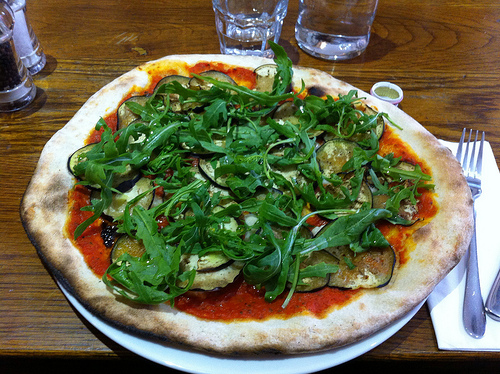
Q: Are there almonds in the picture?
A: No, there are no almonds.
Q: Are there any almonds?
A: No, there are no almonds.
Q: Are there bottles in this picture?
A: No, there are no bottles.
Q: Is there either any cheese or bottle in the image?
A: No, there are no bottles or cheese.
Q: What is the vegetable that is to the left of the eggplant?
A: The vegetable is spinach.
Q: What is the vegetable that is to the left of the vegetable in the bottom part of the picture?
A: The vegetable is spinach.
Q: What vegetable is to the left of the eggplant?
A: The vegetable is spinach.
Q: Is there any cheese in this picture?
A: No, there is no cheese.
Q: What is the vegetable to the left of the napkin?
A: The vegetable is spinach.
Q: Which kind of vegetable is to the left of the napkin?
A: The vegetable is spinach.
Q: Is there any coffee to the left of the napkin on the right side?
A: No, there is spinach to the left of the napkin.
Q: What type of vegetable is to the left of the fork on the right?
A: The vegetable is spinach.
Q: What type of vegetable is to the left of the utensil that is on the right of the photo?
A: The vegetable is spinach.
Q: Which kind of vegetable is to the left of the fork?
A: The vegetable is spinach.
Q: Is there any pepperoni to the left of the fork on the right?
A: No, there is spinach to the left of the fork.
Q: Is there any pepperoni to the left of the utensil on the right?
A: No, there is spinach to the left of the fork.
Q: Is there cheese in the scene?
A: No, there is no cheese.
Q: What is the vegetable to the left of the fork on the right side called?
A: The vegetable is spinach.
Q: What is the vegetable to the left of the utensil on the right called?
A: The vegetable is spinach.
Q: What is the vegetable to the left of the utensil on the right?
A: The vegetable is spinach.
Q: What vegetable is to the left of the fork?
A: The vegetable is spinach.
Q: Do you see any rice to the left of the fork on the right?
A: No, there is spinach to the left of the fork.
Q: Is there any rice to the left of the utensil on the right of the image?
A: No, there is spinach to the left of the fork.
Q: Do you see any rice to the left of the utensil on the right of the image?
A: No, there is spinach to the left of the fork.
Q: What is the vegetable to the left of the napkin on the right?
A: The vegetable is spinach.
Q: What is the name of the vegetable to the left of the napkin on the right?
A: The vegetable is spinach.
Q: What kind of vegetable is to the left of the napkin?
A: The vegetable is spinach.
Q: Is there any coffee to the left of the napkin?
A: No, there is spinach to the left of the napkin.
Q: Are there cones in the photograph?
A: No, there are no cones.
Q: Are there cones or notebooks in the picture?
A: No, there are no cones or notebooks.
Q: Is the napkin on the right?
A: Yes, the napkin is on the right of the image.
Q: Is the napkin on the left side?
A: No, the napkin is on the right of the image.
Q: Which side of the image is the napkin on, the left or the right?
A: The napkin is on the right of the image.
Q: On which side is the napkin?
A: The napkin is on the right of the image.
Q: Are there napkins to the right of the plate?
A: Yes, there is a napkin to the right of the plate.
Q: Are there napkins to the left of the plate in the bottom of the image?
A: No, the napkin is to the right of the plate.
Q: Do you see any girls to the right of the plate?
A: No, there is a napkin to the right of the plate.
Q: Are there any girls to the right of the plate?
A: No, there is a napkin to the right of the plate.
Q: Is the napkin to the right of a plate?
A: Yes, the napkin is to the right of a plate.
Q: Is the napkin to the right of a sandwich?
A: No, the napkin is to the right of a plate.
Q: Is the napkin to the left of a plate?
A: No, the napkin is to the right of a plate.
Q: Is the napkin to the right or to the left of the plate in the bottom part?
A: The napkin is to the right of the plate.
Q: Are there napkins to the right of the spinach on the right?
A: Yes, there is a napkin to the right of the spinach.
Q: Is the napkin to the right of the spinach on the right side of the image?
A: Yes, the napkin is to the right of the spinach.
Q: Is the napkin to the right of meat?
A: No, the napkin is to the right of the spinach.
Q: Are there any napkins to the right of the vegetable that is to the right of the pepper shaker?
A: Yes, there is a napkin to the right of the vegetable.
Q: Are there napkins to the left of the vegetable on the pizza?
A: No, the napkin is to the right of the vegetable.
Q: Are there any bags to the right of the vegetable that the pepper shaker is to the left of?
A: No, there is a napkin to the right of the vegetable.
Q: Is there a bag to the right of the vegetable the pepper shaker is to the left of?
A: No, there is a napkin to the right of the vegetable.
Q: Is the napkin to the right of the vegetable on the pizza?
A: Yes, the napkin is to the right of the vegetable.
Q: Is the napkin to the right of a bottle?
A: No, the napkin is to the right of the vegetable.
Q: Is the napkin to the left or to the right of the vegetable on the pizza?
A: The napkin is to the right of the vegetable.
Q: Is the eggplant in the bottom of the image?
A: Yes, the eggplant is in the bottom of the image.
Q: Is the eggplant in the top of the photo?
A: No, the eggplant is in the bottom of the image.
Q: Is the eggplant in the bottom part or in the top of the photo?
A: The eggplant is in the bottom of the image.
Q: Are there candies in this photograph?
A: No, there are no candies.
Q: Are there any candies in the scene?
A: No, there are no candies.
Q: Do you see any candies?
A: No, there are no candies.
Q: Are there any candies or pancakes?
A: No, there are no candies or pancakes.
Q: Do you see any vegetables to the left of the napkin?
A: Yes, there is a vegetable to the left of the napkin.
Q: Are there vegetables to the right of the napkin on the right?
A: No, the vegetable is to the left of the napkin.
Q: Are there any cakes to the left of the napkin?
A: No, there is a vegetable to the left of the napkin.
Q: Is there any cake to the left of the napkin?
A: No, there is a vegetable to the left of the napkin.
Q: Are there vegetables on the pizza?
A: Yes, there is a vegetable on the pizza.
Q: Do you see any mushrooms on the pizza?
A: No, there is a vegetable on the pizza.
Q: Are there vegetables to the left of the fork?
A: Yes, there is a vegetable to the left of the fork.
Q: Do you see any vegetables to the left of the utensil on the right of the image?
A: Yes, there is a vegetable to the left of the fork.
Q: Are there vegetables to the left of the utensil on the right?
A: Yes, there is a vegetable to the left of the fork.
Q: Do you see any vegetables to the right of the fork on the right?
A: No, the vegetable is to the left of the fork.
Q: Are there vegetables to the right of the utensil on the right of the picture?
A: No, the vegetable is to the left of the fork.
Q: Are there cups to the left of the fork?
A: No, there is a vegetable to the left of the fork.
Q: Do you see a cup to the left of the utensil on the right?
A: No, there is a vegetable to the left of the fork.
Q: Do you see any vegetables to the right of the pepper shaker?
A: Yes, there is a vegetable to the right of the pepper shaker.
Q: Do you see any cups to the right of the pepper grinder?
A: No, there is a vegetable to the right of the pepper grinder.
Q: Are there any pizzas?
A: Yes, there is a pizza.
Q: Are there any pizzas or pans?
A: Yes, there is a pizza.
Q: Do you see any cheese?
A: No, there is no cheese.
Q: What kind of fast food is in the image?
A: The fast food is a pizza.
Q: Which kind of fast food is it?
A: The food is a pizza.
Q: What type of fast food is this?
A: This is a pizza.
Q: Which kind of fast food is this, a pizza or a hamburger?
A: This is a pizza.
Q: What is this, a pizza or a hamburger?
A: This is a pizza.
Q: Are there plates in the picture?
A: Yes, there is a plate.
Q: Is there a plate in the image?
A: Yes, there is a plate.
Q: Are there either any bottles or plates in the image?
A: Yes, there is a plate.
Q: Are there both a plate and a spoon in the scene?
A: No, there is a plate but no spoons.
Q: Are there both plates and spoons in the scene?
A: No, there is a plate but no spoons.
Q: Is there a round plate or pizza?
A: Yes, there is a round plate.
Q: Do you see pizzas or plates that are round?
A: Yes, the plate is round.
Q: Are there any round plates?
A: Yes, there is a round plate.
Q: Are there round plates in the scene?
A: Yes, there is a round plate.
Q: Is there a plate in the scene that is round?
A: Yes, there is a plate that is round.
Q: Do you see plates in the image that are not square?
A: Yes, there is a round plate.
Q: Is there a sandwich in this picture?
A: No, there are no sandwiches.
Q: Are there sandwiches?
A: No, there are no sandwiches.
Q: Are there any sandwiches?
A: No, there are no sandwiches.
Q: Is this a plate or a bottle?
A: This is a plate.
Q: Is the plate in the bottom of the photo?
A: Yes, the plate is in the bottom of the image.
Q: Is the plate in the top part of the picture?
A: No, the plate is in the bottom of the image.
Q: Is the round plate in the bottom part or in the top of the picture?
A: The plate is in the bottom of the image.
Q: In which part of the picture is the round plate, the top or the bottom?
A: The plate is in the bottom of the image.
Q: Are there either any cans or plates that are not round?
A: No, there is a plate but it is round.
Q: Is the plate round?
A: Yes, the plate is round.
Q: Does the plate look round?
A: Yes, the plate is round.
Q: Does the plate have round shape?
A: Yes, the plate is round.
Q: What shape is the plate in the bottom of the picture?
A: The plate is round.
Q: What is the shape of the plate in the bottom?
A: The plate is round.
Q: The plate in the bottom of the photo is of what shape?
A: The plate is round.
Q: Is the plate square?
A: No, the plate is round.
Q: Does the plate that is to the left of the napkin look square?
A: No, the plate is round.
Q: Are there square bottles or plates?
A: No, there is a plate but it is round.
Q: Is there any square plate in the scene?
A: No, there is a plate but it is round.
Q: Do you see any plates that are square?
A: No, there is a plate but it is round.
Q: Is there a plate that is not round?
A: No, there is a plate but it is round.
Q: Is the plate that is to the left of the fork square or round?
A: The plate is round.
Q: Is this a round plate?
A: Yes, this is a round plate.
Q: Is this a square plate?
A: No, this is a round plate.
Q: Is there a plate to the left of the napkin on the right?
A: Yes, there is a plate to the left of the napkin.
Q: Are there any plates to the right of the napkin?
A: No, the plate is to the left of the napkin.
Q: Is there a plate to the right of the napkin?
A: No, the plate is to the left of the napkin.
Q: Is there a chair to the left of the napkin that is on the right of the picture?
A: No, there is a plate to the left of the napkin.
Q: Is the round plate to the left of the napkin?
A: Yes, the plate is to the left of the napkin.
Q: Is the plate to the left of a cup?
A: No, the plate is to the left of the napkin.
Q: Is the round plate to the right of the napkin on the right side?
A: No, the plate is to the left of the napkin.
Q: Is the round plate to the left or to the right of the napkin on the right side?
A: The plate is to the left of the napkin.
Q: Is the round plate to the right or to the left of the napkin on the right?
A: The plate is to the left of the napkin.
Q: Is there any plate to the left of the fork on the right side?
A: Yes, there is a plate to the left of the fork.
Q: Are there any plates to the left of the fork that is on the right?
A: Yes, there is a plate to the left of the fork.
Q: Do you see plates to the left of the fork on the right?
A: Yes, there is a plate to the left of the fork.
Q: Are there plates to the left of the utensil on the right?
A: Yes, there is a plate to the left of the fork.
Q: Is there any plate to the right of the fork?
A: No, the plate is to the left of the fork.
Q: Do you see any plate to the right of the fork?
A: No, the plate is to the left of the fork.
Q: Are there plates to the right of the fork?
A: No, the plate is to the left of the fork.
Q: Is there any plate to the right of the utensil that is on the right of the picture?
A: No, the plate is to the left of the fork.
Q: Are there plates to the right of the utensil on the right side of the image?
A: No, the plate is to the left of the fork.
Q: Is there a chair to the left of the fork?
A: No, there is a plate to the left of the fork.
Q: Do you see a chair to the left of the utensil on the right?
A: No, there is a plate to the left of the fork.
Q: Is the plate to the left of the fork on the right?
A: Yes, the plate is to the left of the fork.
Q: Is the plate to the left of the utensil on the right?
A: Yes, the plate is to the left of the fork.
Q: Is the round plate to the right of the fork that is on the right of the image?
A: No, the plate is to the left of the fork.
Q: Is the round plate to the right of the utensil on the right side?
A: No, the plate is to the left of the fork.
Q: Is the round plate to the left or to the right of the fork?
A: The plate is to the left of the fork.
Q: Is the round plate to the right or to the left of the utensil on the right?
A: The plate is to the left of the fork.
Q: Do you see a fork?
A: Yes, there is a fork.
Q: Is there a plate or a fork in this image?
A: Yes, there is a fork.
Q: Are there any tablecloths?
A: No, there are no tablecloths.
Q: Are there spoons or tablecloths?
A: No, there are no tablecloths or spoons.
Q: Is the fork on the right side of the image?
A: Yes, the fork is on the right of the image.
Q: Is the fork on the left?
A: No, the fork is on the right of the image.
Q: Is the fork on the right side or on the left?
A: The fork is on the right of the image.